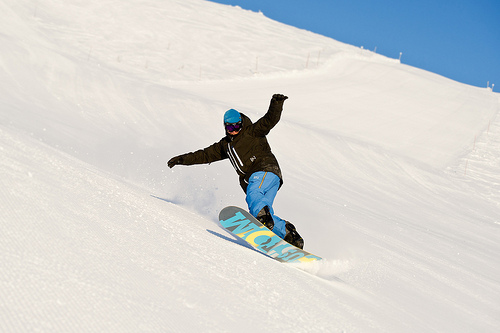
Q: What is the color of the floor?
A: White.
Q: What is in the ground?
A: Snow.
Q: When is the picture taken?
A: Daytime.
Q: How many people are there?
A: 1.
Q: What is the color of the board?
A: Blue and black.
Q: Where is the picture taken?
A: Ski slope.